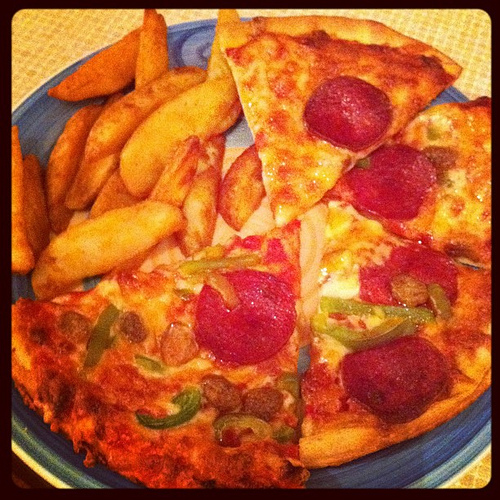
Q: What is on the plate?
A: Pizza and potato wedges.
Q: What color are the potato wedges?
A: Yellow and brown.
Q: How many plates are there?
A: One.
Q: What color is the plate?
A: Blue and white.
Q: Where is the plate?
A: On the table.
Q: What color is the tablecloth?
A: Yellow and white.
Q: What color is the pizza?
A: Red, green, brown, and yellow.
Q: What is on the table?
A: The plate.